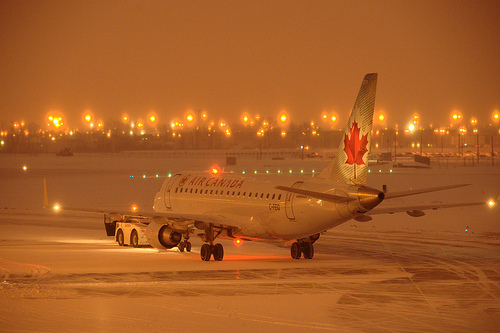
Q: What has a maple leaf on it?
A: Airplane.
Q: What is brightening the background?
A: Lights.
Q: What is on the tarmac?
A: Airplane.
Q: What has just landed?
A: Airplane.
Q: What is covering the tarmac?
A: Snow.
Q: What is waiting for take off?
A: Airplane.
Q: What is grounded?
A: Airplane.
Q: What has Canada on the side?
A: Airplane.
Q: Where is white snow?
A: On the runway.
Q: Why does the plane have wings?
A: To be able to fly.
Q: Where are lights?
A: In the distance.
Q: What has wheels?
A: The plane.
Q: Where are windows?
A: On side of the plane.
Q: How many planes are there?
A: One.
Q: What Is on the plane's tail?
A: Leaf.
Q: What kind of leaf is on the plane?
A: Maple.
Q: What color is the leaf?
A: Red.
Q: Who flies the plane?
A: Pilot.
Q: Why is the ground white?
A: Snow.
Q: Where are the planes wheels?
A: Underneath its body.